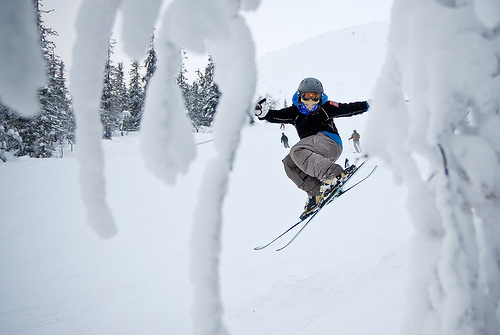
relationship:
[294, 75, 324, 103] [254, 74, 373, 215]
helmet on skier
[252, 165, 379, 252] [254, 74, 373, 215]
ski on skier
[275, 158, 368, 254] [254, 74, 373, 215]
ski on skier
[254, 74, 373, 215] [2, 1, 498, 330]
skier on mountain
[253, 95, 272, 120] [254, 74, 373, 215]
glove on skier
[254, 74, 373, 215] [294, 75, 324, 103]
skier wearing helmet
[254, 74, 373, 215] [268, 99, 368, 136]
skier wearing jacket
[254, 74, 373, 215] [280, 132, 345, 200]
skier wearing pants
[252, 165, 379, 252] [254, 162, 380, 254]
ski in pair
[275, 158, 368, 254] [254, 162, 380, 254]
ski in pair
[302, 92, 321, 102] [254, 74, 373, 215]
goggles on skier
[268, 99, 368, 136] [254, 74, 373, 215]
jacket on skier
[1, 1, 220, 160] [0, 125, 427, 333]
trees in snow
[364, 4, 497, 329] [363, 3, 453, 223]
leaf full of snow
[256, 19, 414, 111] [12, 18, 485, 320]
snow on mountain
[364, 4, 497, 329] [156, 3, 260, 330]
snow on tree branch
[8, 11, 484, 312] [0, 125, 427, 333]
ground covered in snow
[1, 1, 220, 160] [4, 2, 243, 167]
snow covered trees